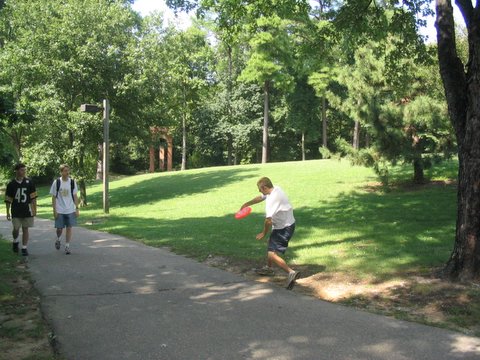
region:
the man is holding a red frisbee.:
[233, 173, 302, 291]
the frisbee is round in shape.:
[236, 206, 252, 219]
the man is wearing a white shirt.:
[236, 175, 304, 289]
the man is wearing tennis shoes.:
[233, 176, 309, 291]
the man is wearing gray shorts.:
[235, 177, 305, 290]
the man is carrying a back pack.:
[49, 163, 82, 254]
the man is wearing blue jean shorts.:
[48, 163, 84, 255]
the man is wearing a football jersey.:
[5, 163, 37, 258]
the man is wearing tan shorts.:
[4, 166, 37, 257]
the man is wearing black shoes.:
[1, 163, 38, 259]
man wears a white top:
[231, 171, 307, 293]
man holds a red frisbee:
[230, 173, 307, 295]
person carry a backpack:
[42, 159, 87, 259]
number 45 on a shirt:
[1, 174, 38, 224]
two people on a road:
[1, 149, 206, 351]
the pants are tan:
[11, 216, 37, 233]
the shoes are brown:
[7, 237, 35, 261]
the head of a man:
[52, 153, 87, 185]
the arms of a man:
[46, 175, 92, 216]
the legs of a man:
[37, 206, 98, 270]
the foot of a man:
[271, 262, 316, 312]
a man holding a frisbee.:
[215, 161, 304, 250]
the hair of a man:
[256, 169, 288, 206]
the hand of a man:
[235, 221, 276, 258]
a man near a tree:
[241, 80, 434, 288]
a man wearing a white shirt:
[233, 169, 323, 259]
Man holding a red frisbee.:
[231, 175, 297, 290]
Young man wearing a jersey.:
[3, 158, 37, 252]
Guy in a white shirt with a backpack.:
[53, 158, 77, 249]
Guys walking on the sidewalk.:
[2, 219, 478, 357]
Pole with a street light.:
[79, 98, 113, 210]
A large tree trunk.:
[421, 0, 477, 281]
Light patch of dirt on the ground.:
[289, 258, 478, 333]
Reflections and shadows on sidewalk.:
[94, 234, 283, 306]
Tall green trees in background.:
[1, 2, 447, 200]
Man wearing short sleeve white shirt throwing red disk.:
[237, 168, 305, 288]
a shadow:
[353, 199, 403, 242]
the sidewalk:
[220, 310, 260, 347]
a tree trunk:
[450, 222, 477, 276]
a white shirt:
[269, 198, 286, 219]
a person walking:
[52, 167, 80, 245]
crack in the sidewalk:
[81, 288, 129, 303]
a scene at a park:
[12, 23, 474, 356]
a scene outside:
[5, 18, 464, 330]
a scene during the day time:
[8, 33, 457, 332]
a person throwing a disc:
[201, 162, 351, 302]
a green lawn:
[64, 140, 476, 295]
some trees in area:
[2, 5, 462, 181]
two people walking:
[1, 142, 91, 253]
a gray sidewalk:
[8, 201, 444, 359]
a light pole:
[72, 85, 123, 230]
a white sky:
[123, 3, 477, 96]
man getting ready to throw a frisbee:
[231, 173, 302, 290]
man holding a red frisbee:
[234, 173, 301, 288]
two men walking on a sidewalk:
[3, 160, 85, 257]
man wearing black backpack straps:
[47, 162, 83, 255]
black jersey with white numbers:
[2, 174, 39, 221]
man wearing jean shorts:
[48, 158, 84, 257]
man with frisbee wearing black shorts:
[233, 173, 300, 293]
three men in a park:
[4, 157, 300, 292]